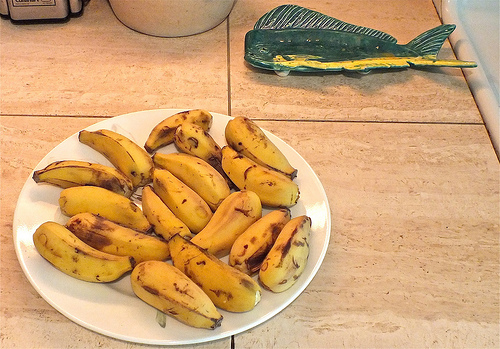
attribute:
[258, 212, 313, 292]
banana — yellow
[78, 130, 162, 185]
banana — yellow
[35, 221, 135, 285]
banana — yellow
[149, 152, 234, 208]
banana — yellow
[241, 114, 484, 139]
line — black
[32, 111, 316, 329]
bananas — yellow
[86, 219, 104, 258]
buising — brown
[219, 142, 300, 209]
banana — small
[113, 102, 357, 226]
plate — circular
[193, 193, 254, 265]
banana — small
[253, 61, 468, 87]
shadow — fish decoration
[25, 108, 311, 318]
food — yellow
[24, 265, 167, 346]
plate — white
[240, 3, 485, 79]
fish decoration — green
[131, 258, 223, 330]
banana — yellow, small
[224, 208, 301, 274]
banana — small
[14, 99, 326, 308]
food product — yellow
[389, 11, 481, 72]
decoration — fish tail, yellow